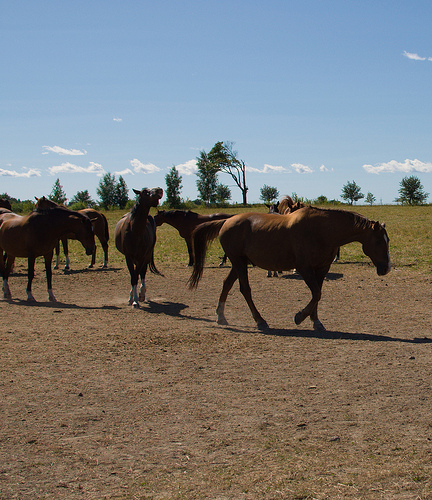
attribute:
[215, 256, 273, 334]
back legs — brown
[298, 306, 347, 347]
hoove — is brown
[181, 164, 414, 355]
horse — brown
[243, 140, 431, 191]
clouds — white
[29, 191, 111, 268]
horse — brown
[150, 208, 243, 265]
horse — brown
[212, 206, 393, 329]
horse — brown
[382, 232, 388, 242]
white strip — fur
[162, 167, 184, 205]
tree — tall, green, leafy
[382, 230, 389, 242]
spot — white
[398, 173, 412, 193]
leaves — green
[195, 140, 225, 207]
leafy tree — tall, green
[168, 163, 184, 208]
leafy tree — tall, green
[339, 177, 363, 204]
leafy tree — tall, green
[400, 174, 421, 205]
leafy tree — tall, green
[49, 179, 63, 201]
leafy tree — tall, green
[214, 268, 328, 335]
legs — four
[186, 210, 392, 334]
horse — brown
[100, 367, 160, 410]
ground — dry, brown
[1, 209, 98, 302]
horse — brown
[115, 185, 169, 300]
horse — brown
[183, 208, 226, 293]
tail — brown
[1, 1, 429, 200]
sky —  is blue,  is clear, blue, clear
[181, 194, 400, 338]
horse — is brown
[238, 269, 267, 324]
leg — brown, white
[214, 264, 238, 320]
leg — brown, white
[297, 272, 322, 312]
leg — brown, white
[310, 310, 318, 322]
leg — brown, white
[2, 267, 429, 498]
dirt — loose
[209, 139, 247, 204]
tree — bare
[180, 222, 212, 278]
tail — brown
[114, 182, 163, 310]
horse — brown